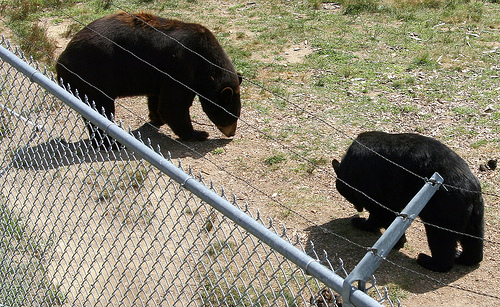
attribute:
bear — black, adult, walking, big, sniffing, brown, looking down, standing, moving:
[56, 14, 243, 150]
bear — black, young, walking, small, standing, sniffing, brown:
[330, 132, 485, 272]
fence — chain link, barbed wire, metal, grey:
[0, 35, 402, 306]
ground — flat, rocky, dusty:
[4, 1, 499, 306]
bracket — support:
[341, 171, 445, 303]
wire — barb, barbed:
[106, 2, 499, 200]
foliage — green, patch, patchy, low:
[1, 0, 499, 119]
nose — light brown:
[228, 131, 236, 137]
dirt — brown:
[1, 154, 499, 304]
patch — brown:
[103, 12, 176, 28]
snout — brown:
[213, 122, 238, 137]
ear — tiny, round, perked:
[221, 86, 234, 100]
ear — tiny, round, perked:
[237, 72, 243, 85]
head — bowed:
[200, 71, 244, 137]